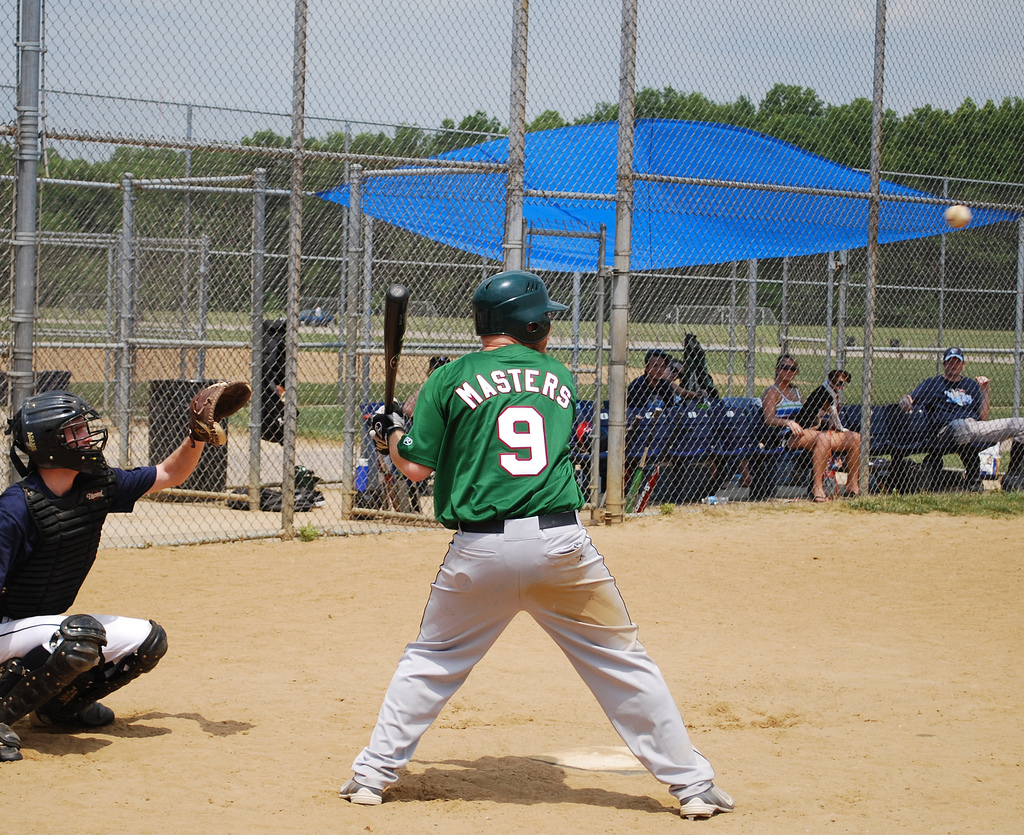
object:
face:
[777, 356, 797, 382]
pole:
[273, 4, 306, 532]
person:
[762, 351, 868, 512]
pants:
[348, 504, 718, 799]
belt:
[460, 510, 579, 533]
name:
[455, 367, 573, 410]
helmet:
[470, 268, 570, 342]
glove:
[186, 381, 250, 447]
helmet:
[3, 389, 117, 488]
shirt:
[3, 453, 162, 624]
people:
[759, 356, 867, 502]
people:
[901, 345, 1019, 492]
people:
[628, 347, 710, 408]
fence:
[0, 3, 1021, 507]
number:
[496, 404, 550, 475]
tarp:
[317, 117, 1018, 272]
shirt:
[401, 348, 585, 518]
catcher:
[0, 372, 252, 764]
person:
[667, 358, 704, 398]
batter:
[329, 265, 732, 814]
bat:
[375, 282, 414, 408]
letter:
[454, 380, 483, 410]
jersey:
[402, 346, 594, 523]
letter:
[476, 373, 498, 397]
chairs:
[675, 397, 721, 455]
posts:
[580, 0, 644, 497]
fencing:
[559, 143, 1005, 519]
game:
[17, 71, 1012, 835]